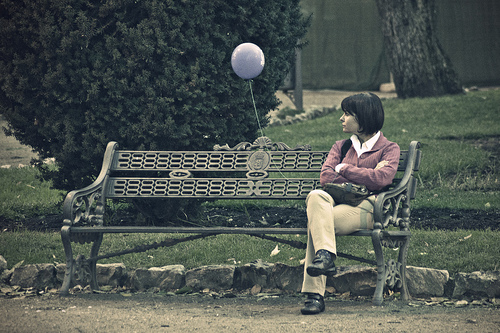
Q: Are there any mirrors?
A: No, there are no mirrors.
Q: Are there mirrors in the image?
A: No, there are no mirrors.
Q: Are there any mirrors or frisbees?
A: No, there are no mirrors or frisbees.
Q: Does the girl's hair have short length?
A: Yes, the hair is short.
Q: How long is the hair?
A: The hair is short.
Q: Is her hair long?
A: No, the hair is short.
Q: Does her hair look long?
A: No, the hair is short.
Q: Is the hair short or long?
A: The hair is short.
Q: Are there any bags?
A: Yes, there is a bag.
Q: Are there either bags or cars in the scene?
A: Yes, there is a bag.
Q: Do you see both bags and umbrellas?
A: No, there is a bag but no umbrellas.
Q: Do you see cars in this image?
A: No, there are no cars.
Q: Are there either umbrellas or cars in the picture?
A: No, there are no cars or umbrellas.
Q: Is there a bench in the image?
A: Yes, there is a bench.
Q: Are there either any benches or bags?
A: Yes, there is a bench.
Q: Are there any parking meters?
A: No, there are no parking meters.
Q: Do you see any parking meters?
A: No, there are no parking meters.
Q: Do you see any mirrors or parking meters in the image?
A: No, there are no parking meters or mirrors.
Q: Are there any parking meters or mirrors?
A: No, there are no parking meters or mirrors.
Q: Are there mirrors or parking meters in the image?
A: No, there are no parking meters or mirrors.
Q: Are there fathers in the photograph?
A: No, there are no fathers.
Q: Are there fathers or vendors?
A: No, there are no fathers or vendors.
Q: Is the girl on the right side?
A: Yes, the girl is on the right of the image.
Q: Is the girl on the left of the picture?
A: No, the girl is on the right of the image.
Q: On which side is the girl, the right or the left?
A: The girl is on the right of the image.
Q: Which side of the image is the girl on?
A: The girl is on the right of the image.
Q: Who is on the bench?
A: The girl is on the bench.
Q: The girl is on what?
A: The girl is on the bench.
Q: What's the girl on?
A: The girl is on the bench.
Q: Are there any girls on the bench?
A: Yes, there is a girl on the bench.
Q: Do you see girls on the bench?
A: Yes, there is a girl on the bench.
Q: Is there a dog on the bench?
A: No, there is a girl on the bench.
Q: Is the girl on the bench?
A: Yes, the girl is on the bench.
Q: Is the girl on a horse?
A: No, the girl is on the bench.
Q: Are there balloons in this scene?
A: Yes, there is a balloon.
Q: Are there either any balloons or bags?
A: Yes, there is a balloon.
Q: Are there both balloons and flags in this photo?
A: No, there is a balloon but no flags.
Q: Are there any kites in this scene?
A: No, there are no kites.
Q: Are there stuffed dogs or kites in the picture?
A: No, there are no kites or stuffed dogs.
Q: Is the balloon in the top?
A: Yes, the balloon is in the top of the image.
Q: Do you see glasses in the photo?
A: No, there are no glasses.